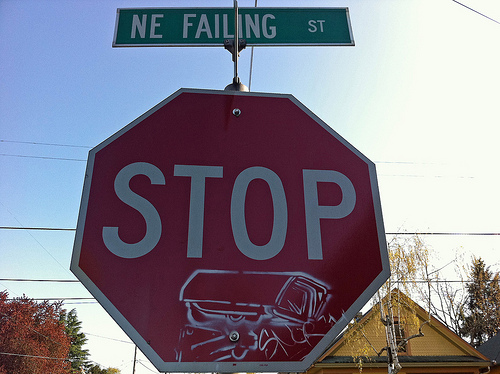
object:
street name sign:
[109, 6, 355, 49]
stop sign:
[68, 87, 391, 373]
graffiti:
[174, 269, 347, 362]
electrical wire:
[0, 225, 499, 236]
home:
[277, 287, 492, 373]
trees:
[451, 258, 499, 345]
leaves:
[46, 301, 61, 309]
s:
[102, 162, 165, 259]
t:
[173, 163, 223, 259]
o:
[230, 165, 288, 260]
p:
[302, 168, 356, 260]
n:
[129, 13, 147, 39]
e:
[149, 15, 165, 39]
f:
[182, 13, 197, 39]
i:
[214, 14, 220, 38]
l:
[222, 13, 234, 38]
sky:
[0, 0, 499, 373]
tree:
[58, 307, 89, 374]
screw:
[231, 107, 242, 117]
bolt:
[227, 330, 239, 342]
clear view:
[0, 0, 499, 373]